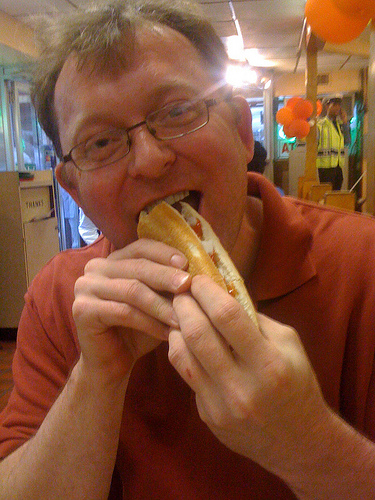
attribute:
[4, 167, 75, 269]
container — trash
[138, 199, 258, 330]
bun — hot dog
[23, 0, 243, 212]
hair — brown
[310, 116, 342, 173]
vest — reflective, safety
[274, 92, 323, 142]
balloons — orange, cluster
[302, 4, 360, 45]
balloons — cluster, orange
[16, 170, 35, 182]
trays — plastic, food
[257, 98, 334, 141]
balloons — orange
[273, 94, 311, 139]
balloons — orange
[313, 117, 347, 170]
vest — yellow, safety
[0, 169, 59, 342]
trash can — inside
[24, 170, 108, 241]
can — restaurant, waste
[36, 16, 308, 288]
man — holding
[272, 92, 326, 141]
balloons — orange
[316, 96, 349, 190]
man — using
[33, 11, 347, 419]
man — eating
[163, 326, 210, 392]
finger — man's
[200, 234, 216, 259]
onion — diced